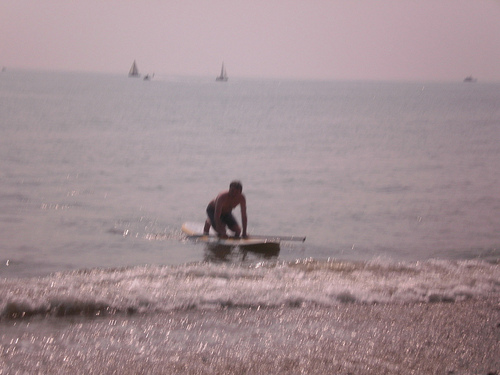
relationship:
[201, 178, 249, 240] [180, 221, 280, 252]
man on surfboard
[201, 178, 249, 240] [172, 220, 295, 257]
man riding surfboard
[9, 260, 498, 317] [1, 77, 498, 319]
wave in water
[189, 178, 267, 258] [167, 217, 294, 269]
man kneeling on surfboard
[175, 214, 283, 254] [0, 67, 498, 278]
surfboard floating on water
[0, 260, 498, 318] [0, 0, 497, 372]
wave floating on water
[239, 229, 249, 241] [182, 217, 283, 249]
hand on surfboard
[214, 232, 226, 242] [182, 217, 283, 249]
hand on surfboard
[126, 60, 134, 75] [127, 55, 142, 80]
sail on boat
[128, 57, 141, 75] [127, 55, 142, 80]
sail on boat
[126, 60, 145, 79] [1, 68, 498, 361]
sailboat in water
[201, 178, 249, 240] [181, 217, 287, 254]
man on surfboard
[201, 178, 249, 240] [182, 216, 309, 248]
man floating on surfboard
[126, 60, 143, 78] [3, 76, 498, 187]
sailboat in ocean